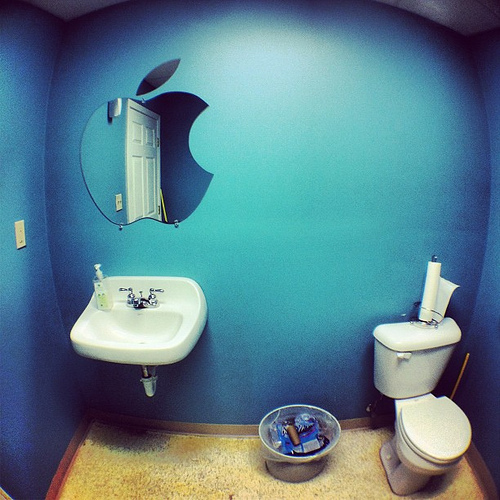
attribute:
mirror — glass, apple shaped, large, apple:
[78, 57, 214, 226]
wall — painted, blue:
[43, 1, 491, 435]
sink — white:
[69, 275, 209, 366]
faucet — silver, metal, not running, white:
[117, 286, 166, 310]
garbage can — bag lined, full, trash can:
[258, 403, 343, 485]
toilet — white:
[371, 316, 474, 497]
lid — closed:
[399, 395, 473, 462]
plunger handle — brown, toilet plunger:
[449, 351, 472, 402]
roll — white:
[419, 262, 461, 322]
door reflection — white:
[125, 98, 164, 225]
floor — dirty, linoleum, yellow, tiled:
[57, 417, 488, 500]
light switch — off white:
[115, 193, 124, 211]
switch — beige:
[13, 219, 27, 249]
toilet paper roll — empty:
[286, 423, 302, 447]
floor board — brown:
[86, 405, 370, 437]